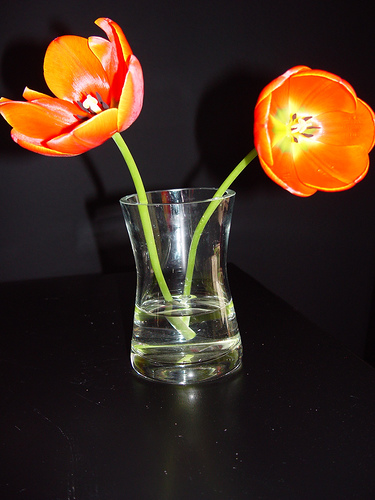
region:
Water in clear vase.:
[134, 300, 244, 384]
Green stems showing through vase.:
[134, 199, 237, 305]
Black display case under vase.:
[70, 393, 334, 479]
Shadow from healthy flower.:
[170, 69, 260, 183]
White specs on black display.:
[223, 432, 251, 472]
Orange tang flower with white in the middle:
[256, 68, 374, 196]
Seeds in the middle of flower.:
[282, 110, 325, 142]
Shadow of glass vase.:
[72, 183, 127, 276]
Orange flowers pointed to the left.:
[4, 24, 147, 157]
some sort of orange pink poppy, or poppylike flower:
[0, 12, 373, 388]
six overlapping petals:
[245, 58, 373, 208]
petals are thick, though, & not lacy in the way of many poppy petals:
[0, 12, 374, 236]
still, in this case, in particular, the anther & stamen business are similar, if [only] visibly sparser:
[67, 87, 125, 130]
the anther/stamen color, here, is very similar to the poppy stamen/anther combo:
[67, 82, 123, 132]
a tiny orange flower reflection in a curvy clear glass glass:
[155, 185, 182, 236]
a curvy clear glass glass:
[111, 181, 249, 403]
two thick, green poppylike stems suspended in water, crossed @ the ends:
[96, 127, 274, 350]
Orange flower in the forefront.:
[248, 59, 372, 205]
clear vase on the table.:
[115, 184, 260, 385]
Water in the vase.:
[124, 297, 248, 386]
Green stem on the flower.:
[109, 130, 195, 338]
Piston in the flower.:
[70, 88, 109, 123]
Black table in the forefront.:
[1, 263, 373, 496]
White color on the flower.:
[81, 90, 101, 113]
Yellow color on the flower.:
[270, 110, 301, 146]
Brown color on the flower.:
[295, 129, 315, 139]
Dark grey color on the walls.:
[3, 0, 373, 361]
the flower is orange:
[256, 65, 371, 239]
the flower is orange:
[242, 57, 335, 221]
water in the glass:
[106, 175, 258, 410]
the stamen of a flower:
[302, 113, 312, 122]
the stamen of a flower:
[305, 125, 321, 131]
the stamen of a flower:
[301, 131, 313, 140]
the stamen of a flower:
[292, 134, 301, 149]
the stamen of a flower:
[92, 89, 103, 103]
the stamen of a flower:
[76, 96, 89, 114]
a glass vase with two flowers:
[111, 182, 261, 398]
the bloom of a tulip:
[2, 11, 158, 154]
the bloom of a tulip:
[244, 54, 373, 212]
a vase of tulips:
[4, 10, 374, 383]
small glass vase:
[112, 180, 255, 388]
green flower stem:
[180, 129, 260, 332]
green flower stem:
[109, 136, 181, 322]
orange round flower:
[253, 56, 373, 203]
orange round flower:
[3, 13, 148, 159]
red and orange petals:
[264, 52, 366, 218]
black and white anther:
[283, 104, 321, 151]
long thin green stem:
[172, 147, 253, 324]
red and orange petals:
[17, 30, 151, 169]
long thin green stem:
[94, 122, 186, 326]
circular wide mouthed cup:
[99, 176, 278, 385]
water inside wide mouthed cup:
[122, 282, 243, 385]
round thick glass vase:
[103, 180, 256, 416]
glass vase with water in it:
[120, 185, 255, 382]